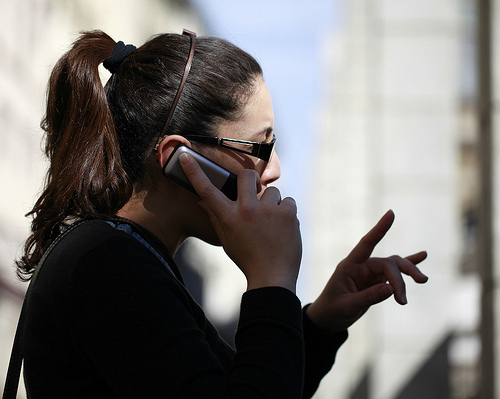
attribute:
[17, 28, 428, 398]
lady — speaking, talking, gesturing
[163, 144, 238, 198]
phone — silver, black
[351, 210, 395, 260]
finger — pointing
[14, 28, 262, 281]
hair — long, brown, pulled back, brunette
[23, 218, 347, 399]
blouse — black, long sleeve, blue, long sleeved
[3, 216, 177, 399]
strap — blue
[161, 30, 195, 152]
band — brown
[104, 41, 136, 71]
holder — blue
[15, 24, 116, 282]
ponytail — brown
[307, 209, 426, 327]
hand — pointing